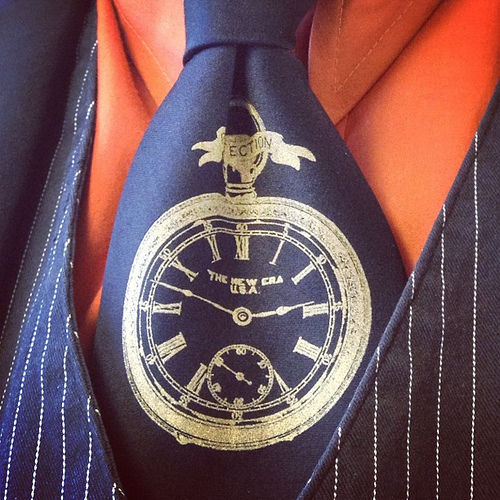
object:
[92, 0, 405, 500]
individual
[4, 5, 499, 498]
vest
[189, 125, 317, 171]
gold flag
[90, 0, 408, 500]
tie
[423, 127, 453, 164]
ground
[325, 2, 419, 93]
orange thread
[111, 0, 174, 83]
orange thread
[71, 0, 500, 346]
orange shirt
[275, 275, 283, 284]
gold words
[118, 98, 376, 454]
design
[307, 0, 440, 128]
collar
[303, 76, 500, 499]
striped suite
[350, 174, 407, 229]
ground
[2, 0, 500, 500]
suit jacket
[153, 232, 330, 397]
roman numeral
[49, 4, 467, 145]
neck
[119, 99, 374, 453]
insignia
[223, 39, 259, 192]
dimple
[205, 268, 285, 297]
writing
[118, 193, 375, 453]
clock